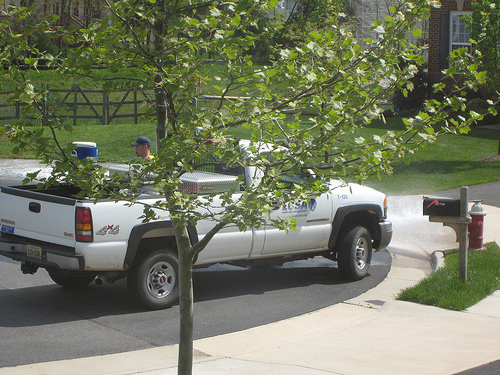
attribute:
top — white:
[456, 186, 468, 221]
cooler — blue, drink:
[61, 134, 111, 181]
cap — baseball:
[130, 134, 153, 151]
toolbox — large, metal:
[121, 163, 248, 211]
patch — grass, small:
[406, 238, 498, 318]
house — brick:
[410, 5, 497, 136]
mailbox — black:
[420, 194, 466, 217]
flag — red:
[424, 195, 444, 210]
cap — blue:
[133, 136, 153, 147]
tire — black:
[125, 249, 193, 308]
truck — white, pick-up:
[4, 129, 397, 318]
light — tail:
[71, 203, 91, 242]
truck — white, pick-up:
[5, 140, 393, 312]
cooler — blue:
[63, 137, 103, 180]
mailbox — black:
[417, 191, 477, 221]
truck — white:
[6, 119, 421, 293]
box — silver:
[146, 162, 254, 229]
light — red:
[70, 199, 113, 262]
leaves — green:
[191, 46, 328, 167]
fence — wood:
[25, 75, 135, 122]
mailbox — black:
[411, 184, 458, 230]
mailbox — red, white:
[458, 194, 492, 260]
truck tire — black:
[342, 220, 372, 276]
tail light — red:
[67, 199, 92, 219]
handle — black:
[20, 202, 50, 222]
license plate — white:
[12, 241, 52, 267]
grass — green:
[425, 270, 469, 302]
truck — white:
[8, 115, 427, 315]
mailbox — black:
[398, 177, 497, 288]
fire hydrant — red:
[469, 207, 491, 257]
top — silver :
[462, 199, 485, 214]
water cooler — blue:
[59, 130, 97, 184]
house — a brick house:
[408, 10, 490, 111]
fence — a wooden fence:
[8, 80, 138, 120]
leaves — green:
[298, 49, 391, 128]